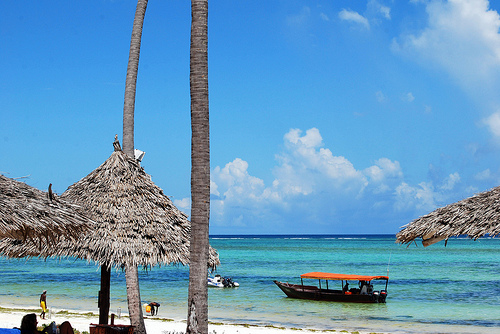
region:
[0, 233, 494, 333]
A clear blue ocean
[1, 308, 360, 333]
A sandy beach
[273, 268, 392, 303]
A boat on the water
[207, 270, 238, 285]
A boat on the water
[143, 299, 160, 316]
A person in the water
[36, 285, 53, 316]
a person in yellow swim trunks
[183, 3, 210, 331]
A long tree trunk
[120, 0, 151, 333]
A long tree trunk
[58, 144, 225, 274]
A straw canopy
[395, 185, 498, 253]
A straw canopy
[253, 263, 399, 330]
a bot on the water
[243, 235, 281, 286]
the water is calm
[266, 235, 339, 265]
the water is calm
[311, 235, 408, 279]
the water is calm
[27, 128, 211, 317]
a roof made of dried leaves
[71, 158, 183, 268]
a roof made of dried leaves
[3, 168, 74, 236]
a roof made of dried leaves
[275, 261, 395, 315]
boat in ocean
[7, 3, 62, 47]
white clouds in blue sky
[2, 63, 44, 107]
white clouds in blue sky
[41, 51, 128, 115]
white clouds in blue sky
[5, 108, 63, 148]
white clouds in blue sky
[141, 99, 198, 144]
white clouds in blue sky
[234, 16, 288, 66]
white clouds in blue sky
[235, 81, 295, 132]
white clouds in blue sky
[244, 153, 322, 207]
white clouds in blue sky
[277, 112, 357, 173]
white clouds in blue sky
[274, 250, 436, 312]
a boat with orange canopy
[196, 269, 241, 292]
a white motor boat in water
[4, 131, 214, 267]
a few umbrellas on beach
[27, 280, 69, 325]
a man in yellow pants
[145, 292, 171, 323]
a person with yellow bucket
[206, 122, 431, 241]
white clouds in the sky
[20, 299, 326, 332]
seaweed on the shore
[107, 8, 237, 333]
two tall tree trunks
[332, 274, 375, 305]
a few people on the brown boat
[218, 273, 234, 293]
black engine on back of boat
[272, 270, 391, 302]
Brown pontoon boat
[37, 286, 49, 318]
Man walking on a beach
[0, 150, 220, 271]
Two umbrellas made of plant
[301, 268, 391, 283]
Orange canopy of a pontoon boat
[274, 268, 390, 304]
Pontoon boat in the ocean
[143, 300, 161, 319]
Person carrying a bucket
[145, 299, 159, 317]
Person bending down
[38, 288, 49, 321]
Dark man in yellow shorts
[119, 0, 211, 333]
Two tall palm tree trunks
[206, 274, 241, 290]
White motorized raft